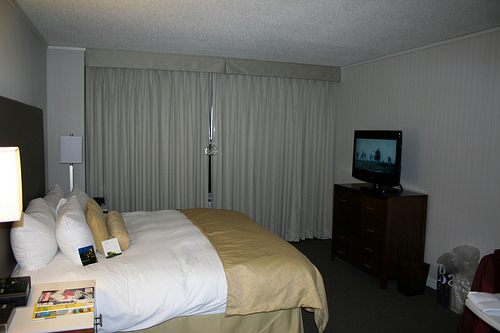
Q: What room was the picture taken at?
A: It was taken at the bedroom.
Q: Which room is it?
A: It is a bedroom.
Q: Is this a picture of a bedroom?
A: Yes, it is showing a bedroom.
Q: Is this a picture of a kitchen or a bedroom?
A: It is showing a bedroom.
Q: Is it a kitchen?
A: No, it is a bedroom.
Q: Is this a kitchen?
A: No, it is a bedroom.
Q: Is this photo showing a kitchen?
A: No, the picture is showing a bedroom.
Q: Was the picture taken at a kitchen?
A: No, the picture was taken in a bedroom.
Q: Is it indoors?
A: Yes, it is indoors.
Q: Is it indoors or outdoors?
A: It is indoors.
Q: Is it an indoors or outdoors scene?
A: It is indoors.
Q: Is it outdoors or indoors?
A: It is indoors.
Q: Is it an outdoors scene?
A: No, it is indoors.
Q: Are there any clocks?
A: Yes, there is a clock.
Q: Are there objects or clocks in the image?
A: Yes, there is a clock.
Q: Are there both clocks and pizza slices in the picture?
A: No, there is a clock but no pizza slices.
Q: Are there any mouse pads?
A: No, there are no mouse pads.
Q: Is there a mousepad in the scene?
A: No, there are no mouse pads.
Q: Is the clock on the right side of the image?
A: No, the clock is on the left of the image.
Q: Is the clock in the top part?
A: No, the clock is in the bottom of the image.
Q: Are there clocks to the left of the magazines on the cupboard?
A: Yes, there is a clock to the left of the magazines.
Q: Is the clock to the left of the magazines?
A: Yes, the clock is to the left of the magazines.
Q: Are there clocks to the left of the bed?
A: Yes, there is a clock to the left of the bed.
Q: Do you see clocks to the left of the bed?
A: Yes, there is a clock to the left of the bed.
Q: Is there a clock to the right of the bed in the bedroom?
A: No, the clock is to the left of the bed.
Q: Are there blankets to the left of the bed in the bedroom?
A: No, there is a clock to the left of the bed.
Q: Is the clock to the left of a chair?
A: No, the clock is to the left of the bed.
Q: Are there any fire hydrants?
A: No, there are no fire hydrants.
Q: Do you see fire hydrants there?
A: No, there are no fire hydrants.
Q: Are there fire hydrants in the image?
A: No, there are no fire hydrants.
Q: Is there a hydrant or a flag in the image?
A: No, there are no fire hydrants or flags.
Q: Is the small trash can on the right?
A: Yes, the garbage can is on the right of the image.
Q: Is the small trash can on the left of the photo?
A: No, the trash bin is on the right of the image.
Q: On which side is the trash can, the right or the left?
A: The trash can is on the right of the image.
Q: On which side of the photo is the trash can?
A: The trash can is on the right of the image.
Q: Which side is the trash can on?
A: The trash can is on the right of the image.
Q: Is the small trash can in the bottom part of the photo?
A: Yes, the garbage bin is in the bottom of the image.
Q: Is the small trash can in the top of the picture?
A: No, the trash bin is in the bottom of the image.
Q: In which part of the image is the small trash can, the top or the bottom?
A: The trashcan is in the bottom of the image.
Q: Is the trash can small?
A: Yes, the trash can is small.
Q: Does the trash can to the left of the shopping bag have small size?
A: Yes, the trash bin is small.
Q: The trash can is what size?
A: The trash can is small.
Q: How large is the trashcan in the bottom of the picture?
A: The garbage can is small.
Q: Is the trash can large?
A: No, the trash can is small.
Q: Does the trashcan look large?
A: No, the trashcan is small.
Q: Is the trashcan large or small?
A: The trashcan is small.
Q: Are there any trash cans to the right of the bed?
A: Yes, there is a trash can to the right of the bed.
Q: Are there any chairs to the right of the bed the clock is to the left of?
A: No, there is a trash can to the right of the bed.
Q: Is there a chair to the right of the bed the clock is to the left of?
A: No, there is a trash can to the right of the bed.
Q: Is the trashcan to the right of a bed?
A: Yes, the trashcan is to the right of a bed.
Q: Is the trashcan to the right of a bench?
A: No, the trashcan is to the right of a bed.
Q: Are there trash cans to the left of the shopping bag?
A: Yes, there is a trash can to the left of the shopping bag.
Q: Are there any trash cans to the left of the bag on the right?
A: Yes, there is a trash can to the left of the shopping bag.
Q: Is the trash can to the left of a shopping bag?
A: Yes, the trash can is to the left of a shopping bag.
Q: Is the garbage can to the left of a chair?
A: No, the garbage can is to the left of a shopping bag.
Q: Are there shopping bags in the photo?
A: Yes, there is a shopping bag.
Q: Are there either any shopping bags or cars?
A: Yes, there is a shopping bag.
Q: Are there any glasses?
A: No, there are no glasses.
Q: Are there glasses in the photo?
A: No, there are no glasses.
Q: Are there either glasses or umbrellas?
A: No, there are no glasses or umbrellas.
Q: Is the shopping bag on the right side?
A: Yes, the shopping bag is on the right of the image.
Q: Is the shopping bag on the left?
A: No, the shopping bag is on the right of the image.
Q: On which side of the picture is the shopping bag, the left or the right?
A: The shopping bag is on the right of the image.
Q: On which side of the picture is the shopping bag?
A: The shopping bag is on the right of the image.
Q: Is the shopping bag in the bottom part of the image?
A: Yes, the shopping bag is in the bottom of the image.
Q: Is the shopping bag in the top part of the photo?
A: No, the shopping bag is in the bottom of the image.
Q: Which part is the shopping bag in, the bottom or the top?
A: The shopping bag is in the bottom of the image.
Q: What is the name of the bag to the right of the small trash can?
A: The bag is a shopping bag.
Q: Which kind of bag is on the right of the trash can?
A: The bag is a shopping bag.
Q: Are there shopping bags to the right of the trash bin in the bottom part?
A: Yes, there is a shopping bag to the right of the garbage can.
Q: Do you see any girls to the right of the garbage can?
A: No, there is a shopping bag to the right of the garbage can.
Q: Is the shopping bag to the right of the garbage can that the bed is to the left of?
A: Yes, the shopping bag is to the right of the garbage can.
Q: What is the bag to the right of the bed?
A: The bag is a shopping bag.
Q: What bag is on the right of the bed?
A: The bag is a shopping bag.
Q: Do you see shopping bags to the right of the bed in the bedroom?
A: Yes, there is a shopping bag to the right of the bed.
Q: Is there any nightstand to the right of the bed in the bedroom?
A: No, there is a shopping bag to the right of the bed.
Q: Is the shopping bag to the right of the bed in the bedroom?
A: Yes, the shopping bag is to the right of the bed.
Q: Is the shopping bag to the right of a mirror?
A: No, the shopping bag is to the right of the bed.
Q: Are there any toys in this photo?
A: No, there are no toys.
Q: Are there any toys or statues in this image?
A: No, there are no toys or statues.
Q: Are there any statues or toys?
A: No, there are no toys or statues.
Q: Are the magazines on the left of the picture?
A: Yes, the magazines are on the left of the image.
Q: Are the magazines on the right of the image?
A: No, the magazines are on the left of the image.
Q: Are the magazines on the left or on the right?
A: The magazines are on the left of the image.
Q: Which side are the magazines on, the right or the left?
A: The magazines are on the left of the image.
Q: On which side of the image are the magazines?
A: The magazines are on the left of the image.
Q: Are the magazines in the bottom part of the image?
A: Yes, the magazines are in the bottom of the image.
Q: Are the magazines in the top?
A: No, the magazines are in the bottom of the image.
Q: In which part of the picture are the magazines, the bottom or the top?
A: The magazines are in the bottom of the image.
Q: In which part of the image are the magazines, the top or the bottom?
A: The magazines are in the bottom of the image.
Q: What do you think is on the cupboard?
A: The magazines are on the cupboard.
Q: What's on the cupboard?
A: The magazines are on the cupboard.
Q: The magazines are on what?
A: The magazines are on the cupboard.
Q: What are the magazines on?
A: The magazines are on the cupboard.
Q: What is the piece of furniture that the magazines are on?
A: The piece of furniture is a cupboard.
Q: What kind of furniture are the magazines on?
A: The magazines are on the cupboard.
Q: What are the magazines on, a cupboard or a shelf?
A: The magazines are on a cupboard.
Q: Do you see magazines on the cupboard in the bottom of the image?
A: Yes, there are magazines on the cupboard.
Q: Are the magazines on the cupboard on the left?
A: Yes, the magazines are on the cupboard.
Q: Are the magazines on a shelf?
A: No, the magazines are on the cupboard.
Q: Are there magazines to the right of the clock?
A: Yes, there are magazines to the right of the clock.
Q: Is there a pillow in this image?
A: Yes, there are pillows.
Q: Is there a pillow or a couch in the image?
A: Yes, there are pillows.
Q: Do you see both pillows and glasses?
A: No, there are pillows but no glasses.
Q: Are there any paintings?
A: No, there are no paintings.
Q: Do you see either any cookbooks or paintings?
A: No, there are no paintings or cookbooks.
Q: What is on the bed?
A: The pillows are on the bed.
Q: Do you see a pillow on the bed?
A: Yes, there are pillows on the bed.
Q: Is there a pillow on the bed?
A: Yes, there are pillows on the bed.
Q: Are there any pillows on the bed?
A: Yes, there are pillows on the bed.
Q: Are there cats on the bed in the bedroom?
A: No, there are pillows on the bed.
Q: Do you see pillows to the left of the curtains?
A: Yes, there are pillows to the left of the curtains.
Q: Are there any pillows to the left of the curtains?
A: Yes, there are pillows to the left of the curtains.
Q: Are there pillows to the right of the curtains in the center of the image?
A: No, the pillows are to the left of the curtains.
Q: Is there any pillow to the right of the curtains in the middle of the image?
A: No, the pillows are to the left of the curtains.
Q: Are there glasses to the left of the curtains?
A: No, there are pillows to the left of the curtains.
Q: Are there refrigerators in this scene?
A: No, there are no refrigerators.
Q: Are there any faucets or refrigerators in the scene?
A: No, there are no refrigerators or faucets.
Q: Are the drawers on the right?
A: Yes, the drawers are on the right of the image.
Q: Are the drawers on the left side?
A: No, the drawers are on the right of the image.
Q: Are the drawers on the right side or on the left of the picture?
A: The drawers are on the right of the image.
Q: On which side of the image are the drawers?
A: The drawers are on the right of the image.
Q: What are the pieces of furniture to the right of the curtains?
A: The pieces of furniture are drawers.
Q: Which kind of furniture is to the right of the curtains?
A: The pieces of furniture are drawers.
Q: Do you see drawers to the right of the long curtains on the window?
A: Yes, there are drawers to the right of the curtains.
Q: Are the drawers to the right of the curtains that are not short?
A: Yes, the drawers are to the right of the curtains.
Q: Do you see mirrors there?
A: No, there are no mirrors.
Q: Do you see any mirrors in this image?
A: No, there are no mirrors.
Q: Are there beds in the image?
A: Yes, there is a bed.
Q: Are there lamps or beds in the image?
A: Yes, there is a bed.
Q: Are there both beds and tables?
A: Yes, there are both a bed and a table.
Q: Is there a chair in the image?
A: No, there are no chairs.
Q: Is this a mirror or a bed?
A: This is a bed.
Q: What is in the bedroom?
A: The bed is in the bedroom.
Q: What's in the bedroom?
A: The bed is in the bedroom.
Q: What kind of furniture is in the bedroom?
A: The piece of furniture is a bed.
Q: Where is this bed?
A: The bed is in the bedroom.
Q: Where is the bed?
A: The bed is in the bedroom.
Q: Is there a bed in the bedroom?
A: Yes, there is a bed in the bedroom.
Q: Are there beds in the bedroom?
A: Yes, there is a bed in the bedroom.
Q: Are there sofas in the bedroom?
A: No, there is a bed in the bedroom.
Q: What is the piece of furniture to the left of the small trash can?
A: The piece of furniture is a bed.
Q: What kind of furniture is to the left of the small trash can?
A: The piece of furniture is a bed.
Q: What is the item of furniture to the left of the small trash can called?
A: The piece of furniture is a bed.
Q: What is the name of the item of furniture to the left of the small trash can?
A: The piece of furniture is a bed.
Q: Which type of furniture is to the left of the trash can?
A: The piece of furniture is a bed.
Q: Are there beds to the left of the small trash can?
A: Yes, there is a bed to the left of the garbage bin.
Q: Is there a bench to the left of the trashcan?
A: No, there is a bed to the left of the trashcan.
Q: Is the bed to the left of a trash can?
A: Yes, the bed is to the left of a trash can.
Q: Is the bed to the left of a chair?
A: No, the bed is to the left of a trash can.